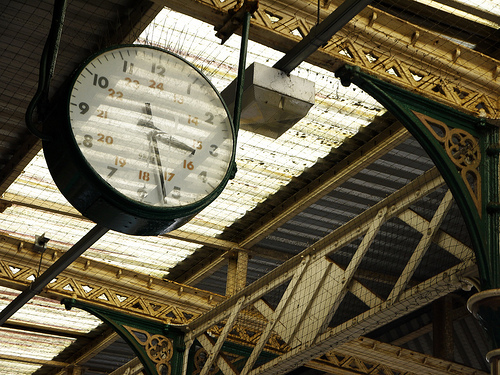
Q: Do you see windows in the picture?
A: Yes, there is a window.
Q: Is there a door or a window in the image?
A: Yes, there is a window.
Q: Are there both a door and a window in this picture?
A: No, there is a window but no doors.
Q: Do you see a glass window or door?
A: Yes, there is a glass window.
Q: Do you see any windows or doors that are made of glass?
A: Yes, the window is made of glass.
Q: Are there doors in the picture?
A: No, there are no doors.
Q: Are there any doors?
A: No, there are no doors.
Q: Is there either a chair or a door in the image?
A: No, there are no doors or chairs.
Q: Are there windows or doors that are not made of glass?
A: No, there is a window but it is made of glass.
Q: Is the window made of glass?
A: Yes, the window is made of glass.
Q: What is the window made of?
A: The window is made of glass.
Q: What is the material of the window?
A: The window is made of glass.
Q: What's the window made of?
A: The window is made of glass.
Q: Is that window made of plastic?
A: No, the window is made of glass.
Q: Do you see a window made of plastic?
A: No, there is a window but it is made of glass.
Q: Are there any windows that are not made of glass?
A: No, there is a window but it is made of glass.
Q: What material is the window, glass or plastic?
A: The window is made of glass.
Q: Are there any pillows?
A: No, there are no pillows.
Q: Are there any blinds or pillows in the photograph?
A: No, there are no pillows or blinds.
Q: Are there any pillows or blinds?
A: No, there are no pillows or blinds.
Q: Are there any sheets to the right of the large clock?
A: Yes, there is a sheet to the right of the clock.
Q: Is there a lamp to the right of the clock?
A: No, there is a sheet to the right of the clock.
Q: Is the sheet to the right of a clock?
A: Yes, the sheet is to the right of a clock.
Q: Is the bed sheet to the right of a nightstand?
A: No, the bed sheet is to the right of a clock.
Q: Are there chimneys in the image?
A: No, there are no chimneys.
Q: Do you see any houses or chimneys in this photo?
A: No, there are no chimneys or houses.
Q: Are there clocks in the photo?
A: Yes, there is a clock.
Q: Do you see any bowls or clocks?
A: Yes, there is a clock.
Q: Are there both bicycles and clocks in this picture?
A: No, there is a clock but no bicycles.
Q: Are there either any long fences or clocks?
A: Yes, there is a long clock.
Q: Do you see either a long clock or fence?
A: Yes, there is a long clock.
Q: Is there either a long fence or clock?
A: Yes, there is a long clock.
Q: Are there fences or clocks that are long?
A: Yes, the clock is long.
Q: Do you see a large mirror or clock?
A: Yes, there is a large clock.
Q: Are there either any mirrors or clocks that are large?
A: Yes, the clock is large.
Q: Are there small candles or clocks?
A: Yes, there is a small clock.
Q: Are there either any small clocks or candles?
A: Yes, there is a small clock.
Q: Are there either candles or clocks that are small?
A: Yes, the clock is small.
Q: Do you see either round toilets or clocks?
A: Yes, there is a round clock.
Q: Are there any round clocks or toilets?
A: Yes, there is a round clock.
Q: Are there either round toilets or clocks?
A: Yes, there is a round clock.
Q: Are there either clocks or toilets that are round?
A: Yes, the clock is round.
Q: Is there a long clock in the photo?
A: Yes, there is a long clock.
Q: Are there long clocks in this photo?
A: Yes, there is a long clock.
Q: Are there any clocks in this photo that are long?
A: Yes, there is a clock that is long.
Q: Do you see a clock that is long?
A: Yes, there is a clock that is long.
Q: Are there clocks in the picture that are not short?
A: Yes, there is a long clock.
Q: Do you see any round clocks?
A: Yes, there is a round clock.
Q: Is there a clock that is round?
A: Yes, there is a clock that is round.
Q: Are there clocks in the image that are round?
A: Yes, there is a clock that is round.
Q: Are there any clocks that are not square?
A: Yes, there is a round clock.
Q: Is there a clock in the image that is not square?
A: Yes, there is a round clock.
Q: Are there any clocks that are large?
A: Yes, there is a large clock.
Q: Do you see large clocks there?
A: Yes, there is a large clock.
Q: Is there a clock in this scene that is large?
A: Yes, there is a clock that is large.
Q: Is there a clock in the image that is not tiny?
A: Yes, there is a large clock.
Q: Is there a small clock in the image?
A: Yes, there is a small clock.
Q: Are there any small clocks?
A: Yes, there is a small clock.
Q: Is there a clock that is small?
A: Yes, there is a clock that is small.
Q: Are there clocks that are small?
A: Yes, there is a clock that is small.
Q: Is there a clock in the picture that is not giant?
A: Yes, there is a small clock.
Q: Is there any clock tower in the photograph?
A: No, there are no clock towers.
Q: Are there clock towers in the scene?
A: No, there are no clock towers.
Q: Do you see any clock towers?
A: No, there are no clock towers.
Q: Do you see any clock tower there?
A: No, there are no clock towers.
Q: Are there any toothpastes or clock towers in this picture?
A: No, there are no clock towers or toothpastes.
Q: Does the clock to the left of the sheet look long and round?
A: Yes, the clock is long and round.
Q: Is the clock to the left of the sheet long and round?
A: Yes, the clock is long and round.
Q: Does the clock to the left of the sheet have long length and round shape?
A: Yes, the clock is long and round.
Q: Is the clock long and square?
A: No, the clock is long but round.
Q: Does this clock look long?
A: Yes, the clock is long.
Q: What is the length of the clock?
A: The clock is long.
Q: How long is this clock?
A: The clock is long.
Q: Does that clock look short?
A: No, the clock is long.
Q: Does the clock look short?
A: No, the clock is long.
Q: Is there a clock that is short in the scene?
A: No, there is a clock but it is long.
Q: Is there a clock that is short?
A: No, there is a clock but it is long.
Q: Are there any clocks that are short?
A: No, there is a clock but it is long.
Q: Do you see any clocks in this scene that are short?
A: No, there is a clock but it is long.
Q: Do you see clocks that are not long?
A: No, there is a clock but it is long.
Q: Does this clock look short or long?
A: The clock is long.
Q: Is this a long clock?
A: Yes, this is a long clock.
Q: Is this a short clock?
A: No, this is a long clock.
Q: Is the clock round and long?
A: Yes, the clock is round and long.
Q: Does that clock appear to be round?
A: Yes, the clock is round.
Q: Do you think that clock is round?
A: Yes, the clock is round.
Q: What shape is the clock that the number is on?
A: The clock is round.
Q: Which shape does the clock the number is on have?
A: The clock has round shape.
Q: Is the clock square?
A: No, the clock is round.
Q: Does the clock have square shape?
A: No, the clock is round.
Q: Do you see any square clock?
A: No, there is a clock but it is round.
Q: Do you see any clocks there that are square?
A: No, there is a clock but it is round.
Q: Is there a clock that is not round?
A: No, there is a clock but it is round.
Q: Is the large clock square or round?
A: The clock is round.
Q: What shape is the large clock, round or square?
A: The clock is round.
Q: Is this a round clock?
A: Yes, this is a round clock.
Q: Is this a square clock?
A: No, this is a round clock.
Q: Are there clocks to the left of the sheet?
A: Yes, there is a clock to the left of the sheet.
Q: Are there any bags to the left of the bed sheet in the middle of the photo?
A: No, there is a clock to the left of the sheet.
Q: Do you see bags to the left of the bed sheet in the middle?
A: No, there is a clock to the left of the sheet.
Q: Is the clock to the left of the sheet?
A: Yes, the clock is to the left of the sheet.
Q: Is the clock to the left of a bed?
A: No, the clock is to the left of the sheet.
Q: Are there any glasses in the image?
A: No, there are no glasses.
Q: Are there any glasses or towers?
A: No, there are no glasses or towers.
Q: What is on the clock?
A: The number is on the clock.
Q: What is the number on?
A: The number is on the clock.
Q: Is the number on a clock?
A: Yes, the number is on a clock.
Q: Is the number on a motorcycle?
A: No, the number is on a clock.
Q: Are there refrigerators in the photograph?
A: No, there are no refrigerators.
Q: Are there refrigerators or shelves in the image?
A: No, there are no refrigerators or shelves.